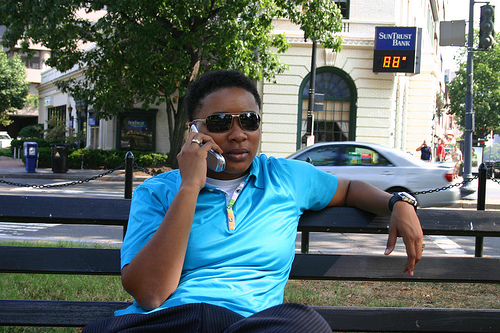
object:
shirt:
[113, 153, 337, 317]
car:
[267, 140, 458, 208]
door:
[290, 145, 339, 182]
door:
[338, 145, 402, 193]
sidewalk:
[0, 138, 499, 197]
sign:
[370, 25, 422, 76]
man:
[83, 67, 420, 331]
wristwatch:
[391, 187, 423, 208]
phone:
[188, 123, 226, 172]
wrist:
[378, 190, 415, 213]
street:
[0, 181, 499, 253]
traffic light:
[478, 35, 495, 50]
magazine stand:
[23, 141, 38, 172]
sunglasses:
[187, 110, 264, 133]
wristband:
[374, 182, 404, 217]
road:
[0, 159, 500, 258]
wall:
[251, 19, 297, 161]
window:
[296, 65, 357, 149]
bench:
[0, 195, 500, 333]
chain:
[1, 163, 123, 191]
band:
[388, 194, 402, 212]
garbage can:
[50, 143, 70, 173]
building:
[32, 0, 499, 169]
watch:
[387, 191, 419, 211]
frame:
[295, 65, 358, 153]